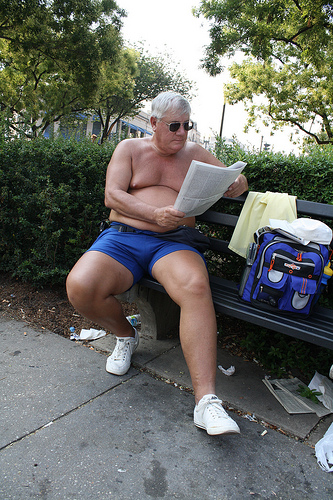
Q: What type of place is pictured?
A: It is a pavement.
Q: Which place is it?
A: It is a pavement.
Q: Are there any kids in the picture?
A: No, there are no kids.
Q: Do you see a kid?
A: No, there are no children.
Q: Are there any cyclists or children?
A: No, there are no children or cyclists.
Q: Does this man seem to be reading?
A: Yes, the man is reading.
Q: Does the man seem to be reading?
A: Yes, the man is reading.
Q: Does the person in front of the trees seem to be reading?
A: Yes, the man is reading.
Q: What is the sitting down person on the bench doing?
A: The man is reading.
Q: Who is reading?
A: The man is reading.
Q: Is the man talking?
A: No, the man is reading.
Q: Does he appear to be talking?
A: No, the man is reading.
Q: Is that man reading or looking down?
A: The man is reading.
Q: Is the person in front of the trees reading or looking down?
A: The man is reading.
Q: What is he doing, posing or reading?
A: The man is reading.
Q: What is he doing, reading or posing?
A: The man is reading.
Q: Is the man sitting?
A: Yes, the man is sitting.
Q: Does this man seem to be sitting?
A: Yes, the man is sitting.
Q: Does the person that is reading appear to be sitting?
A: Yes, the man is sitting.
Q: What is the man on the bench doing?
A: The man is sitting.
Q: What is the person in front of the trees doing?
A: The man is sitting.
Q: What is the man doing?
A: The man is sitting.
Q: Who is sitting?
A: The man is sitting.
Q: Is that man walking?
A: No, the man is sitting.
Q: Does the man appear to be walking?
A: No, the man is sitting.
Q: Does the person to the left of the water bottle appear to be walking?
A: No, the man is sitting.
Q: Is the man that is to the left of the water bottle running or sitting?
A: The man is sitting.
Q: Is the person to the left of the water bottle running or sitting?
A: The man is sitting.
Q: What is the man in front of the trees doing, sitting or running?
A: The man is sitting.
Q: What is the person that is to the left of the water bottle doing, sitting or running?
A: The man is sitting.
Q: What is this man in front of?
A: The man is in front of the trees.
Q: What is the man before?
A: The man is in front of the trees.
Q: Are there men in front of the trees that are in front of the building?
A: Yes, there is a man in front of the trees.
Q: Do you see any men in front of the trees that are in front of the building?
A: Yes, there is a man in front of the trees.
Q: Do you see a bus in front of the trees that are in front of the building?
A: No, there is a man in front of the trees.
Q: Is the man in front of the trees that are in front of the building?
A: Yes, the man is in front of the trees.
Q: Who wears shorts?
A: The man wears shorts.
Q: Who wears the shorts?
A: The man wears shorts.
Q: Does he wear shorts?
A: Yes, the man wears shorts.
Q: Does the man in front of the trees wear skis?
A: No, the man wears shorts.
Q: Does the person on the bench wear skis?
A: No, the man wears shorts.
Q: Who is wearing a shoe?
A: The man is wearing a shoe.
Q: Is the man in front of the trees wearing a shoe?
A: Yes, the man is wearing a shoe.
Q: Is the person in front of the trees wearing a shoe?
A: Yes, the man is wearing a shoe.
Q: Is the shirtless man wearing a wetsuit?
A: No, the man is wearing a shoe.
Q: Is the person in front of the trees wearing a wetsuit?
A: No, the man is wearing a shoe.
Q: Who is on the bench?
A: The man is on the bench.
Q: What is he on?
A: The man is on the bench.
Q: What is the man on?
A: The man is on the bench.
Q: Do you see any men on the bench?
A: Yes, there is a man on the bench.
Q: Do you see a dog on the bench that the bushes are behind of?
A: No, there is a man on the bench.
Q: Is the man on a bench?
A: Yes, the man is on a bench.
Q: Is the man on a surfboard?
A: No, the man is on a bench.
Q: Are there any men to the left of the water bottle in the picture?
A: Yes, there is a man to the left of the water bottle.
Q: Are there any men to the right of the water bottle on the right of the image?
A: No, the man is to the left of the water bottle.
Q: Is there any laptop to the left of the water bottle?
A: No, there is a man to the left of the water bottle.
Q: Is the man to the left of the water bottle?
A: Yes, the man is to the left of the water bottle.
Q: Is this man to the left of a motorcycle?
A: No, the man is to the left of the water bottle.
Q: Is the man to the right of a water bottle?
A: No, the man is to the left of a water bottle.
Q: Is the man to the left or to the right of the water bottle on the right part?
A: The man is to the left of the water bottle.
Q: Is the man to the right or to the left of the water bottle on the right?
A: The man is to the left of the water bottle.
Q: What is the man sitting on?
A: The man is sitting on the bench.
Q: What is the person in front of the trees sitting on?
A: The man is sitting on the bench.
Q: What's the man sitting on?
A: The man is sitting on the bench.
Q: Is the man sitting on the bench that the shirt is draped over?
A: Yes, the man is sitting on the bench.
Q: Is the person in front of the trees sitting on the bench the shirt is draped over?
A: Yes, the man is sitting on the bench.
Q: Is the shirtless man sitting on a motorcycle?
A: No, the man is sitting on the bench.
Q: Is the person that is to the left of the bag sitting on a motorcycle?
A: No, the man is sitting on the bench.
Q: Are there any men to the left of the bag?
A: Yes, there is a man to the left of the bag.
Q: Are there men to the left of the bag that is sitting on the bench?
A: Yes, there is a man to the left of the bag.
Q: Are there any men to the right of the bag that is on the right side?
A: No, the man is to the left of the bag.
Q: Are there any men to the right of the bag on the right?
A: No, the man is to the left of the bag.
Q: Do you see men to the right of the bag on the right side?
A: No, the man is to the left of the bag.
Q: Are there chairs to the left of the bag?
A: No, there is a man to the left of the bag.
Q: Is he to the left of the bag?
A: Yes, the man is to the left of the bag.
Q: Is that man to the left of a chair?
A: No, the man is to the left of the bag.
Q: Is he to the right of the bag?
A: No, the man is to the left of the bag.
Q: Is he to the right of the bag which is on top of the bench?
A: No, the man is to the left of the bag.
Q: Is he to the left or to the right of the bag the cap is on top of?
A: The man is to the left of the bag.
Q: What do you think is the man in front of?
A: The man is in front of the trees.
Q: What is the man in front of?
A: The man is in front of the trees.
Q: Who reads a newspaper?
A: The man reads a newspaper.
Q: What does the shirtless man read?
A: The man reads a newspaper.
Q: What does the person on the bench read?
A: The man reads a newspaper.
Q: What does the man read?
A: The man reads a newspaper.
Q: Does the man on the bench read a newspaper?
A: Yes, the man reads a newspaper.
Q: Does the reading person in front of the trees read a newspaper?
A: Yes, the man reads a newspaper.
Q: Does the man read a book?
A: No, the man reads a newspaper.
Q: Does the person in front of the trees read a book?
A: No, the man reads a newspaper.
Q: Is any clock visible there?
A: No, there are no clocks.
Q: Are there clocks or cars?
A: No, there are no clocks or cars.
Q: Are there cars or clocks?
A: No, there are no clocks or cars.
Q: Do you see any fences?
A: No, there are no fences.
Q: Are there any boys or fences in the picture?
A: No, there are no fences or boys.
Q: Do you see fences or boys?
A: No, there are no fences or boys.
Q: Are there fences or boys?
A: No, there are no fences or boys.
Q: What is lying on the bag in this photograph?
A: The cap is lying on the bag.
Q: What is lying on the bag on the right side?
A: The cap is lying on the bag.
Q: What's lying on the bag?
A: The cap is lying on the bag.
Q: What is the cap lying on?
A: The cap is lying on the bag.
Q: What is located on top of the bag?
A: The cap is on top of the bag.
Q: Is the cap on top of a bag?
A: Yes, the cap is on top of a bag.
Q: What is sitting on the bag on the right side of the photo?
A: The cap is sitting on the bag.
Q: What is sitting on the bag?
A: The cap is sitting on the bag.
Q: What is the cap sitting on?
A: The cap is sitting on the bag.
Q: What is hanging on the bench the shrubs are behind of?
A: The shirt is hanging on the bench.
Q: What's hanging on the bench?
A: The shirt is hanging on the bench.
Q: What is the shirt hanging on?
A: The shirt is hanging on the bench.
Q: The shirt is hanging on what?
A: The shirt is hanging on the bench.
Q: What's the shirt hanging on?
A: The shirt is hanging on the bench.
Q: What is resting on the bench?
A: The shirt is resting on the bench.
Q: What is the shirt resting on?
A: The shirt is resting on the bench.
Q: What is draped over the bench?
A: The shirt is draped over the bench.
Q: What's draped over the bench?
A: The shirt is draped over the bench.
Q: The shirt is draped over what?
A: The shirt is draped over the bench.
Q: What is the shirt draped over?
A: The shirt is draped over the bench.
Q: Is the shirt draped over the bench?
A: Yes, the shirt is draped over the bench.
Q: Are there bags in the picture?
A: Yes, there is a bag.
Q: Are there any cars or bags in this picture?
A: Yes, there is a bag.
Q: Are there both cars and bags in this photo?
A: No, there is a bag but no cars.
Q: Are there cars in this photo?
A: No, there are no cars.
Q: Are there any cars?
A: No, there are no cars.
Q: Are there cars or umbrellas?
A: No, there are no cars or umbrellas.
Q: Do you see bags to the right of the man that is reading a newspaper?
A: Yes, there is a bag to the right of the man.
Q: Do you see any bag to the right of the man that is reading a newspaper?
A: Yes, there is a bag to the right of the man.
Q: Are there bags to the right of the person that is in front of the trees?
A: Yes, there is a bag to the right of the man.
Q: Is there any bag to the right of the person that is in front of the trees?
A: Yes, there is a bag to the right of the man.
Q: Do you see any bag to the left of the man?
A: No, the bag is to the right of the man.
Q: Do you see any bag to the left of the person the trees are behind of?
A: No, the bag is to the right of the man.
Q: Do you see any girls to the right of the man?
A: No, there is a bag to the right of the man.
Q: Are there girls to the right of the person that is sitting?
A: No, there is a bag to the right of the man.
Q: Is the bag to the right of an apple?
A: No, the bag is to the right of the man.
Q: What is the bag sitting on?
A: The bag is sitting on the bench.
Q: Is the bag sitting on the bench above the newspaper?
A: Yes, the bag is sitting on the bench.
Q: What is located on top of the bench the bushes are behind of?
A: The bag is on top of the bench.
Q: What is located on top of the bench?
A: The bag is on top of the bench.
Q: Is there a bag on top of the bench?
A: Yes, there is a bag on top of the bench.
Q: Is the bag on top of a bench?
A: Yes, the bag is on top of a bench.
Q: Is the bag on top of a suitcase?
A: No, the bag is on top of a bench.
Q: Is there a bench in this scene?
A: Yes, there is a bench.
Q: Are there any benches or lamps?
A: Yes, there is a bench.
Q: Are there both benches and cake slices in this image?
A: No, there is a bench but no cake slices.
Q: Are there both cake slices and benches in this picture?
A: No, there is a bench but no cake slices.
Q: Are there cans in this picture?
A: No, there are no cans.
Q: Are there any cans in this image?
A: No, there are no cans.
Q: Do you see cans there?
A: No, there are no cans.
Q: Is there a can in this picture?
A: No, there are no cans.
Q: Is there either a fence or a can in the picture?
A: No, there are no cans or fences.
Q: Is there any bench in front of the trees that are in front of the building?
A: Yes, there is a bench in front of the trees.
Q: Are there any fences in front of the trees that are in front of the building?
A: No, there is a bench in front of the trees.